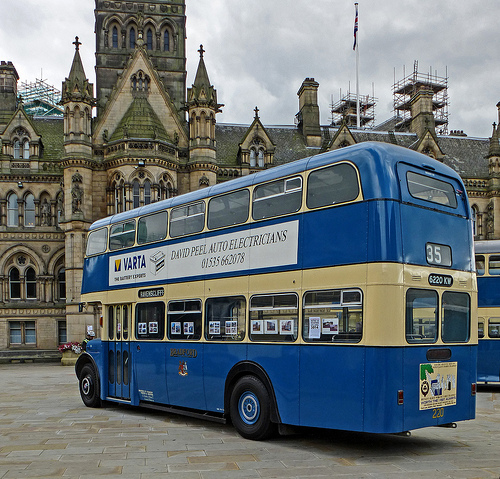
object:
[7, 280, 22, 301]
window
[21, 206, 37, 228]
window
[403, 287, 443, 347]
window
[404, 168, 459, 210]
window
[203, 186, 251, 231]
window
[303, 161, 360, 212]
window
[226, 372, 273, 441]
tire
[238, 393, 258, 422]
rim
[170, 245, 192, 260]
david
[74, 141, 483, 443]
bus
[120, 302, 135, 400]
door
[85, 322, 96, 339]
flowers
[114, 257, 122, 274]
logo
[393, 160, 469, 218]
curve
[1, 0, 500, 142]
sky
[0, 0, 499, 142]
cloud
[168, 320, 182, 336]
sticker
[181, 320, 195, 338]
sticker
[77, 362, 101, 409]
wheel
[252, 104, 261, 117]
cross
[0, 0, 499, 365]
building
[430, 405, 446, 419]
number 220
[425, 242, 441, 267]
number 35